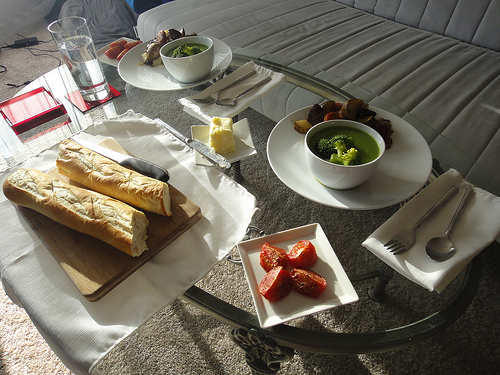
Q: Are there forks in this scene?
A: Yes, there is a fork.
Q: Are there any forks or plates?
A: Yes, there is a fork.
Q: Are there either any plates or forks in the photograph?
A: Yes, there is a fork.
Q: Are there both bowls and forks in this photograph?
A: Yes, there are both a fork and a bowl.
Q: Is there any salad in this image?
A: No, there is no salad.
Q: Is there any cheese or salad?
A: No, there are no salad or cheese.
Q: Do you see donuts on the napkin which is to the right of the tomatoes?
A: No, there is a fork on the napkin.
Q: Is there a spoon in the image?
A: Yes, there is a spoon.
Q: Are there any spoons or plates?
A: Yes, there is a spoon.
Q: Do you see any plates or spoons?
A: Yes, there is a spoon.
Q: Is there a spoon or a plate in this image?
A: Yes, there is a spoon.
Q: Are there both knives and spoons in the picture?
A: Yes, there are both a spoon and a knife.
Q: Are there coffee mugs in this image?
A: No, there are no coffee mugs.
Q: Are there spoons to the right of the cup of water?
A: Yes, there is a spoon to the right of the cup.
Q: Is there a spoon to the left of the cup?
A: No, the spoon is to the right of the cup.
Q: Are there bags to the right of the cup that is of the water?
A: No, there is a spoon to the right of the cup.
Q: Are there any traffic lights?
A: No, there are no traffic lights.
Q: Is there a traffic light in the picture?
A: No, there are no traffic lights.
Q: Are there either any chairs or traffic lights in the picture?
A: No, there are no traffic lights or chairs.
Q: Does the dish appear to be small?
A: Yes, the dish is small.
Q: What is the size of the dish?
A: The dish is small.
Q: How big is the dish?
A: The dish is small.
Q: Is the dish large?
A: No, the dish is small.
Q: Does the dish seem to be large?
A: No, the dish is small.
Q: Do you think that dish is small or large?
A: The dish is small.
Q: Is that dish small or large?
A: The dish is small.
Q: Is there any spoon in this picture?
A: Yes, there is a spoon.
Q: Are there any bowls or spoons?
A: Yes, there is a spoon.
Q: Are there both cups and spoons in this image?
A: Yes, there are both a spoon and a cup.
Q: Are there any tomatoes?
A: Yes, there are tomatoes.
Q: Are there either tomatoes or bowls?
A: Yes, there are tomatoes.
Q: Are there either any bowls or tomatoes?
A: Yes, there are tomatoes.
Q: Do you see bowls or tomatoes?
A: Yes, there are tomatoes.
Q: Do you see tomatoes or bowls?
A: Yes, there are tomatoes.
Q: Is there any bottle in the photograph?
A: No, there are no bottles.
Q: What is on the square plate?
A: The tomatoes are on the plate.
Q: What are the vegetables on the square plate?
A: The vegetables are tomatoes.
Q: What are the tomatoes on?
A: The tomatoes are on the plate.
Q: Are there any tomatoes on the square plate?
A: Yes, there are tomatoes on the plate.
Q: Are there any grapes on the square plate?
A: No, there are tomatoes on the plate.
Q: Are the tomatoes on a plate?
A: Yes, the tomatoes are on a plate.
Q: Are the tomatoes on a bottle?
A: No, the tomatoes are on a plate.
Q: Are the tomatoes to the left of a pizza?
A: No, the tomatoes are to the left of the napkin.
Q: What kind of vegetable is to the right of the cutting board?
A: The vegetables are tomatoes.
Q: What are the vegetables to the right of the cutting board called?
A: The vegetables are tomatoes.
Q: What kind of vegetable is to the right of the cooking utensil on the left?
A: The vegetables are tomatoes.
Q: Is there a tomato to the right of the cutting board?
A: Yes, there are tomatoes to the right of the cutting board.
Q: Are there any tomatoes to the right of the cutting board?
A: Yes, there are tomatoes to the right of the cutting board.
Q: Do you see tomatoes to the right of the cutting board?
A: Yes, there are tomatoes to the right of the cutting board.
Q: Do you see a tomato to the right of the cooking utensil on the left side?
A: Yes, there are tomatoes to the right of the cutting board.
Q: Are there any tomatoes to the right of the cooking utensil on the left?
A: Yes, there are tomatoes to the right of the cutting board.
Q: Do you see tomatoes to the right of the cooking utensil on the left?
A: Yes, there are tomatoes to the right of the cutting board.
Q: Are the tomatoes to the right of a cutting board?
A: Yes, the tomatoes are to the right of a cutting board.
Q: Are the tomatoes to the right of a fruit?
A: No, the tomatoes are to the right of a cutting board.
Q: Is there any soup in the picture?
A: Yes, there is soup.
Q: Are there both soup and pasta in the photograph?
A: No, there is soup but no pasta.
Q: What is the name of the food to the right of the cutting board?
A: The food is soup.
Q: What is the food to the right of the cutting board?
A: The food is soup.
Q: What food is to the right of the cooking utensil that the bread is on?
A: The food is soup.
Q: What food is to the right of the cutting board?
A: The food is soup.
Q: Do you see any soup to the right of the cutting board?
A: Yes, there is soup to the right of the cutting board.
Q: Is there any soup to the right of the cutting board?
A: Yes, there is soup to the right of the cutting board.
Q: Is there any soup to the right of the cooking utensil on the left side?
A: Yes, there is soup to the right of the cutting board.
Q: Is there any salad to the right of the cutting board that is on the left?
A: No, there is soup to the right of the cutting board.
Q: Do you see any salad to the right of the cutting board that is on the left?
A: No, there is soup to the right of the cutting board.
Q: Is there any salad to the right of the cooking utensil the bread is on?
A: No, there is soup to the right of the cutting board.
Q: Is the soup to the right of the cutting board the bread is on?
A: Yes, the soup is to the right of the cutting board.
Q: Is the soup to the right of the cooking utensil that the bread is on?
A: Yes, the soup is to the right of the cutting board.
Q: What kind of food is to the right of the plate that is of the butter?
A: The food is soup.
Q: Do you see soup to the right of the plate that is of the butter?
A: Yes, there is soup to the right of the plate.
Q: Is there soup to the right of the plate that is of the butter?
A: Yes, there is soup to the right of the plate.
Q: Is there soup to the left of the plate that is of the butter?
A: No, the soup is to the right of the plate.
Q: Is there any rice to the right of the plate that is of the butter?
A: No, there is soup to the right of the plate.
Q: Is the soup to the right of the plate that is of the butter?
A: Yes, the soup is to the right of the plate.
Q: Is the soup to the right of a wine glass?
A: No, the soup is to the right of the plate.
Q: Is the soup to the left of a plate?
A: No, the soup is to the right of a plate.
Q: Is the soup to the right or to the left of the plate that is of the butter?
A: The soup is to the right of the plate.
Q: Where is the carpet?
A: The carpet is on the floor.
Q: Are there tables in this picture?
A: Yes, there is a table.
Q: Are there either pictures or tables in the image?
A: Yes, there is a table.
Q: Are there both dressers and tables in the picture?
A: No, there is a table but no dressers.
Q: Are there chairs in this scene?
A: No, there are no chairs.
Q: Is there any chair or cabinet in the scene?
A: No, there are no chairs or cabinets.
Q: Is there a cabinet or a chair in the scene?
A: No, there are no chairs or cabinets.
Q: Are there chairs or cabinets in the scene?
A: No, there are no chairs or cabinets.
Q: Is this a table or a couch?
A: This is a table.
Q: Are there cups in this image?
A: Yes, there is a cup.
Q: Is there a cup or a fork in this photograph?
A: Yes, there is a cup.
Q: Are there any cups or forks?
A: Yes, there is a cup.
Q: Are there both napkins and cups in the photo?
A: Yes, there are both a cup and a napkin.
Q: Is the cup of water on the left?
A: Yes, the cup is on the left of the image.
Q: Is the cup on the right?
A: No, the cup is on the left of the image.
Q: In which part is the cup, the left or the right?
A: The cup is on the left of the image.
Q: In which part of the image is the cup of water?
A: The cup is on the left of the image.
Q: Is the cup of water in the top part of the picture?
A: Yes, the cup is in the top of the image.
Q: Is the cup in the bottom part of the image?
A: No, the cup is in the top of the image.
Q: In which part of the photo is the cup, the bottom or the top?
A: The cup is in the top of the image.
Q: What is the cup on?
A: The cup is on the table.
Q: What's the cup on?
A: The cup is on the table.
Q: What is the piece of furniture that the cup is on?
A: The piece of furniture is a table.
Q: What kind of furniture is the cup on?
A: The cup is on the table.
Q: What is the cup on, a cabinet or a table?
A: The cup is on a table.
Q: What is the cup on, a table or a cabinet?
A: The cup is on a table.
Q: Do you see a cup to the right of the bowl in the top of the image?
A: No, the cup is to the left of the bowl.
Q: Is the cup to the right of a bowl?
A: No, the cup is to the left of a bowl.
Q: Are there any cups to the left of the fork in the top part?
A: Yes, there is a cup to the left of the fork.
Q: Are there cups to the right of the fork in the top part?
A: No, the cup is to the left of the fork.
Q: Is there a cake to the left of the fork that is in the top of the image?
A: No, there is a cup to the left of the fork.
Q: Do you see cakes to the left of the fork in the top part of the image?
A: No, there is a cup to the left of the fork.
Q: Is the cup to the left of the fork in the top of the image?
A: Yes, the cup is to the left of the fork.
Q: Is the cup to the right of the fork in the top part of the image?
A: No, the cup is to the left of the fork.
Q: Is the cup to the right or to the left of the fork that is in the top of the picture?
A: The cup is to the left of the fork.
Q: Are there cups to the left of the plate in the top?
A: Yes, there is a cup to the left of the plate.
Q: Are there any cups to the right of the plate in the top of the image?
A: No, the cup is to the left of the plate.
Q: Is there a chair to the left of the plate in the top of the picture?
A: No, there is a cup to the left of the plate.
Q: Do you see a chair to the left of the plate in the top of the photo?
A: No, there is a cup to the left of the plate.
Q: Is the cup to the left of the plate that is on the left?
A: Yes, the cup is to the left of the plate.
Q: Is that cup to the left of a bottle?
A: No, the cup is to the left of the plate.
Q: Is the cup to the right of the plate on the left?
A: No, the cup is to the left of the plate.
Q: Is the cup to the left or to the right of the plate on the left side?
A: The cup is to the left of the plate.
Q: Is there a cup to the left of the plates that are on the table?
A: Yes, there is a cup to the left of the plates.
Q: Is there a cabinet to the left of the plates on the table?
A: No, there is a cup to the left of the plates.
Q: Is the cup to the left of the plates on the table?
A: Yes, the cup is to the left of the plates.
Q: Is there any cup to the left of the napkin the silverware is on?
A: Yes, there is a cup to the left of the napkin.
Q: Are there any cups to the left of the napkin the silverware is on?
A: Yes, there is a cup to the left of the napkin.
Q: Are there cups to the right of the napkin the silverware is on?
A: No, the cup is to the left of the napkin.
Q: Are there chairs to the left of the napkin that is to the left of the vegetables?
A: No, there is a cup to the left of the napkin.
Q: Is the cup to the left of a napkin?
A: Yes, the cup is to the left of a napkin.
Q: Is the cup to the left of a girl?
A: No, the cup is to the left of a napkin.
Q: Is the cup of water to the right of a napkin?
A: No, the cup is to the left of a napkin.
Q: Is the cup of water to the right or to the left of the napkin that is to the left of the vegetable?
A: The cup is to the left of the napkin.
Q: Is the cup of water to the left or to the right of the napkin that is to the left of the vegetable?
A: The cup is to the left of the napkin.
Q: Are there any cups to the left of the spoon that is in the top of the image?
A: Yes, there is a cup to the left of the spoon.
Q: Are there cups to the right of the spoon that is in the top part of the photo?
A: No, the cup is to the left of the spoon.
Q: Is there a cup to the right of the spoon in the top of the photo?
A: No, the cup is to the left of the spoon.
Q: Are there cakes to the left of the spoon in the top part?
A: No, there is a cup to the left of the spoon.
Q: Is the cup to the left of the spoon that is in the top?
A: Yes, the cup is to the left of the spoon.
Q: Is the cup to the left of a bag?
A: No, the cup is to the left of the spoon.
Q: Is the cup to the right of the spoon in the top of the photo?
A: No, the cup is to the left of the spoon.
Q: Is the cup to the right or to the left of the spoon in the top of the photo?
A: The cup is to the left of the spoon.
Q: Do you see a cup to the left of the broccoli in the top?
A: Yes, there is a cup to the left of the broccoli.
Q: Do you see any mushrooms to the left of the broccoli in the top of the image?
A: No, there is a cup to the left of the broccoli.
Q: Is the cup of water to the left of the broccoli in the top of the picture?
A: Yes, the cup is to the left of the broccoli.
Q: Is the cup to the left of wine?
A: No, the cup is to the left of the broccoli.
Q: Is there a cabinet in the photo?
A: No, there are no cabinets.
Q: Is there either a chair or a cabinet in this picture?
A: No, there are no cabinets or chairs.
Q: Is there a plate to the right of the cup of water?
A: Yes, there are plates to the right of the cup.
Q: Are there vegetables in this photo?
A: Yes, there are vegetables.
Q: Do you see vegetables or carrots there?
A: Yes, there are vegetables.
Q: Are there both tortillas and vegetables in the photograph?
A: No, there are vegetables but no tortillas.